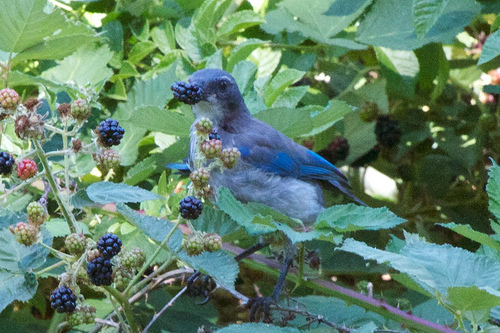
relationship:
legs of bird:
[195, 238, 298, 317] [175, 71, 380, 313]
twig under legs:
[227, 237, 458, 332] [195, 238, 298, 317]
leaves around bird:
[73, 2, 480, 120] [175, 71, 380, 313]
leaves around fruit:
[73, 2, 480, 120] [17, 153, 39, 178]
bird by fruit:
[175, 71, 380, 313] [51, 232, 129, 303]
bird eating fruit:
[175, 71, 380, 313] [174, 80, 203, 108]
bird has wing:
[175, 71, 380, 313] [284, 146, 375, 208]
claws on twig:
[180, 266, 276, 322] [227, 237, 458, 332]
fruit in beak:
[174, 80, 203, 108] [175, 76, 213, 106]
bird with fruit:
[175, 71, 380, 313] [174, 80, 203, 108]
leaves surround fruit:
[73, 2, 480, 120] [189, 120, 242, 186]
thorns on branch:
[39, 168, 58, 221] [34, 144, 101, 238]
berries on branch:
[18, 196, 138, 287] [34, 144, 101, 238]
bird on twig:
[175, 71, 380, 313] [227, 237, 458, 332]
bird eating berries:
[175, 71, 380, 313] [187, 231, 222, 256]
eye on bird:
[216, 75, 239, 94] [175, 71, 380, 313]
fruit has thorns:
[17, 153, 39, 178] [39, 168, 58, 221]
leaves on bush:
[73, 2, 480, 120] [9, 16, 486, 317]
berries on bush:
[187, 231, 222, 256] [9, 16, 486, 317]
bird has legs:
[175, 71, 380, 313] [195, 238, 298, 317]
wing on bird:
[284, 146, 375, 208] [175, 71, 380, 313]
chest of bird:
[219, 155, 311, 215] [175, 71, 380, 313]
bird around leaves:
[175, 71, 380, 313] [73, 2, 480, 120]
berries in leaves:
[187, 231, 222, 256] [73, 2, 480, 120]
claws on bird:
[180, 266, 276, 322] [175, 71, 380, 313]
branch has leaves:
[34, 144, 101, 238] [73, 2, 480, 120]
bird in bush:
[175, 71, 380, 313] [9, 16, 486, 317]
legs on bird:
[195, 238, 298, 317] [175, 71, 380, 313]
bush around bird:
[9, 16, 486, 317] [175, 71, 380, 313]